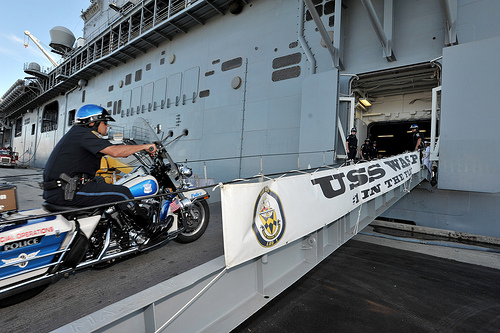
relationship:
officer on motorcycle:
[40, 102, 133, 220] [7, 148, 225, 276]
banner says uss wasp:
[216, 166, 427, 257] [318, 150, 429, 189]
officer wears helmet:
[40, 102, 133, 220] [74, 101, 110, 124]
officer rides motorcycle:
[40, 102, 133, 220] [7, 148, 225, 276]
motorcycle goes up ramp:
[7, 148, 225, 276] [191, 159, 422, 333]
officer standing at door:
[339, 127, 360, 170] [351, 72, 444, 168]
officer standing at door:
[364, 135, 374, 165] [351, 72, 444, 168]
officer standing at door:
[402, 124, 425, 157] [351, 72, 444, 168]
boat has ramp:
[7, 10, 500, 203] [191, 159, 422, 333]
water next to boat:
[376, 229, 494, 256] [7, 10, 500, 203]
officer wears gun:
[40, 102, 133, 220] [58, 171, 80, 203]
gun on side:
[58, 171, 80, 203] [65, 144, 99, 208]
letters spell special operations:
[0, 227, 60, 246] [3, 222, 67, 243]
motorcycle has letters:
[7, 148, 225, 276] [0, 227, 60, 246]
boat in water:
[7, 10, 500, 203] [376, 229, 494, 256]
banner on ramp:
[216, 166, 427, 257] [191, 159, 422, 333]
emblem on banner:
[243, 187, 291, 250] [216, 166, 427, 257]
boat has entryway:
[7, 10, 500, 203] [351, 72, 444, 168]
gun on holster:
[58, 171, 80, 203] [40, 170, 88, 198]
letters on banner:
[314, 168, 396, 199] [216, 166, 427, 257]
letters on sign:
[4, 238, 39, 251] [2, 234, 41, 254]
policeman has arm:
[40, 102, 133, 220] [94, 137, 157, 159]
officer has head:
[40, 98, 175, 241] [75, 104, 112, 138]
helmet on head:
[74, 101, 110, 124] [75, 104, 112, 138]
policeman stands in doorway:
[339, 127, 360, 170] [351, 72, 444, 168]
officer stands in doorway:
[359, 137, 374, 163] [351, 72, 444, 168]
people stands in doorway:
[369, 137, 381, 158] [351, 72, 444, 168]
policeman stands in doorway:
[402, 124, 425, 157] [351, 72, 444, 168]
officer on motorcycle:
[40, 98, 175, 241] [7, 148, 225, 276]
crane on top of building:
[19, 29, 57, 74] [20, 56, 91, 98]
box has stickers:
[1, 184, 20, 212] [0, 194, 7, 211]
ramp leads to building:
[191, 159, 422, 333] [20, 56, 91, 98]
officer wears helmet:
[40, 98, 175, 241] [74, 101, 110, 124]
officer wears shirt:
[40, 98, 175, 241] [41, 123, 107, 178]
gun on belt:
[58, 171, 80, 203] [40, 172, 97, 189]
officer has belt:
[40, 98, 175, 241] [40, 172, 97, 189]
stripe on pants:
[78, 189, 126, 201] [47, 175, 139, 223]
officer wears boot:
[40, 98, 175, 241] [141, 214, 179, 243]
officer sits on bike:
[40, 98, 175, 241] [7, 148, 225, 276]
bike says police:
[7, 148, 225, 276] [4, 238, 39, 251]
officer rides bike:
[40, 98, 175, 241] [7, 148, 225, 276]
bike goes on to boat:
[7, 148, 225, 276] [7, 10, 500, 203]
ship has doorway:
[7, 10, 500, 203] [351, 72, 444, 168]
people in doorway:
[344, 125, 438, 171] [351, 72, 444, 168]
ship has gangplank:
[7, 10, 500, 203] [191, 159, 422, 333]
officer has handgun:
[40, 102, 133, 220] [58, 171, 80, 203]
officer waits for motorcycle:
[343, 126, 360, 165] [7, 148, 225, 276]